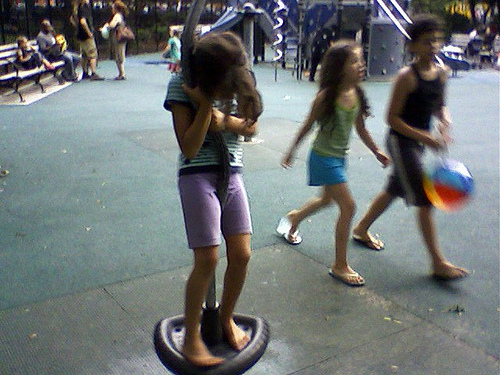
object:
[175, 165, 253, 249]
shorts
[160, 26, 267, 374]
girl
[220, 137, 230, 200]
pogo stick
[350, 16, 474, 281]
boy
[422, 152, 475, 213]
ball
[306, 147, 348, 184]
shorts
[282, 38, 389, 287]
girl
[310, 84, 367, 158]
shirt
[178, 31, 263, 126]
hair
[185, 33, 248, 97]
head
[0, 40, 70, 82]
bench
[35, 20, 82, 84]
person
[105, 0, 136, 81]
woman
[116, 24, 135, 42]
pocketbook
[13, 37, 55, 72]
girl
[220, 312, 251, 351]
foot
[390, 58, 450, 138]
tank top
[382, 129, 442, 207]
shorts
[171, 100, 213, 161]
arm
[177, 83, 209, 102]
hand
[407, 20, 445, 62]
head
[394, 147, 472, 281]
leg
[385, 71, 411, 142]
arm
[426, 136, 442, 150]
hand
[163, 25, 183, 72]
kid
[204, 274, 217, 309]
pole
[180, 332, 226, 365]
foot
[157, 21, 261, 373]
swing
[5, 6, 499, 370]
park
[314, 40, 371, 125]
hair